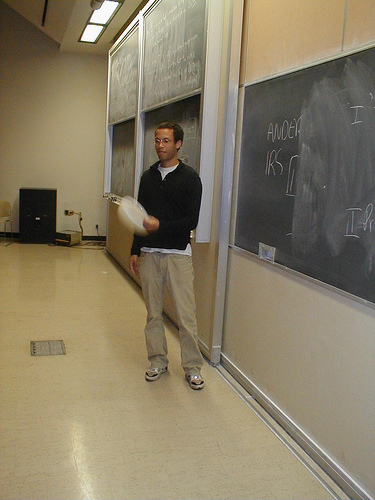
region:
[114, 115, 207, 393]
man holding Frisbee in classroom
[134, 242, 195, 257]
tee shirt hanging out of sweater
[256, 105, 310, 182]
chalk writing on blackboard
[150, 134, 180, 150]
glasses on man's face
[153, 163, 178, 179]
neck of white tee shirt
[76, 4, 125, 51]
two lights on ceiling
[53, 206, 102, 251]
projector on floor with cord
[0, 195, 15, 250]
chair on floor against wall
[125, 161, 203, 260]
black long sleeved sweater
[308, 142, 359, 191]
wiped chalk on blackboard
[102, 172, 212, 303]
the man is carrying a frisbee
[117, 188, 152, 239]
the frisbee is white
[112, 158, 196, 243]
man is wearing a shirt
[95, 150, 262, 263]
the shirt is black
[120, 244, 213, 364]
man is wearing a pants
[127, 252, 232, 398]
the pants are brown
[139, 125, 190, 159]
the man is wearing eyeglasses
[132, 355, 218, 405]
the man is wearing shoes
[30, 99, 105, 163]
the wall is beige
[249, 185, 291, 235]
the board is black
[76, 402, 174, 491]
the floor is waxed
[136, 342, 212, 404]
the man wears shoes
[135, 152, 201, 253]
the shirt is black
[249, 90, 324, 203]
the words are white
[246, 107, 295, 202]
the board is green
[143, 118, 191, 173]
the man wears glasses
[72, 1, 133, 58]
the lights are on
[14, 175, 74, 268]
the speaker is black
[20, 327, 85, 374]
the vent is white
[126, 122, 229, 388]
boy wearing black shirt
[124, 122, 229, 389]
boy wearing tan pants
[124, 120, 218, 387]
boy wearing wire frame glasses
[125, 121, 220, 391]
boy wearing tennis shoes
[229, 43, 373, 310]
black board affixed to the wall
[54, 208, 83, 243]
over head projector on floor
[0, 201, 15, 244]
chair sitting against wall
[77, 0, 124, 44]
sky light windows in ceiling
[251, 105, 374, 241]
words written on blackboard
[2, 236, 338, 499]
tan class room floor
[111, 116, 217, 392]
man holding an object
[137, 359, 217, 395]
white shoes on the mans feet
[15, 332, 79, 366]
vent built into the floor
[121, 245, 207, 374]
beige pants being worn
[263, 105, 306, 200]
chalk writing on the board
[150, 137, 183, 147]
glasses on the mans face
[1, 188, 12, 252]
side of a chair in the background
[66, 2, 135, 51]
light built into the ceiling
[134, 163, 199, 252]
black sweater worn over a white shirt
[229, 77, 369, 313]
black chalkboard on the wall